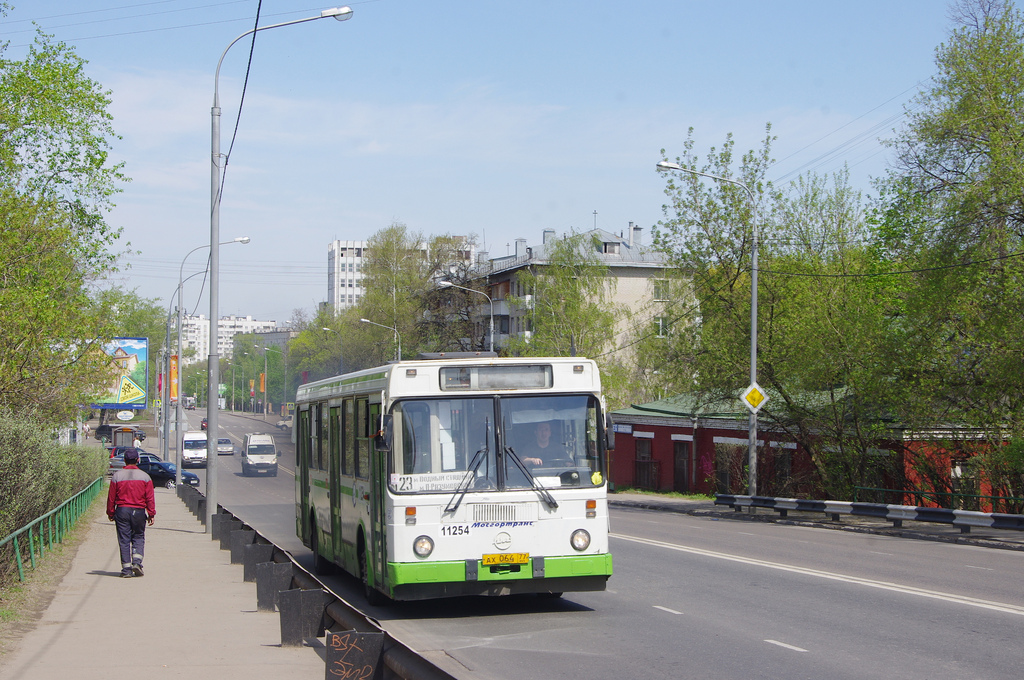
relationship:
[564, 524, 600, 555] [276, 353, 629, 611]
headlight of a bus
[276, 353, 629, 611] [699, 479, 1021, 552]
bus across from road barrier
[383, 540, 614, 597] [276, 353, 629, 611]
bumper of a bus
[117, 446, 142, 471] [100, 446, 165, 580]
head of a man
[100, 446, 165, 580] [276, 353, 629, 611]
man near a bus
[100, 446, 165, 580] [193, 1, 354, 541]
man near a street light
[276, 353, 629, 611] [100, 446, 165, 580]
bus near a man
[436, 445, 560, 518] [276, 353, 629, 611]
windshield wipers of a bus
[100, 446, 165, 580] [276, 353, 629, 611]
man near bus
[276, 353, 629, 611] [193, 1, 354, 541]
bus near a street light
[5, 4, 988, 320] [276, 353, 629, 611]
sky above bus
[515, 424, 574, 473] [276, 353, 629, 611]
driver of a bus